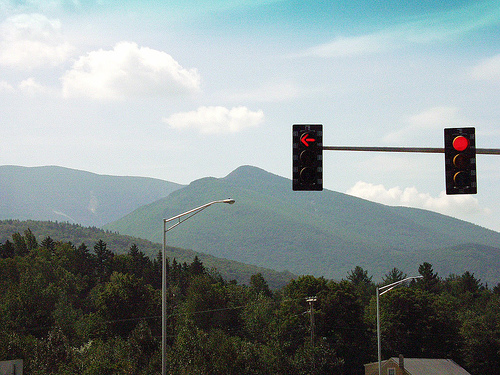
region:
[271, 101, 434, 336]
a traffic light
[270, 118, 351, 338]
a traffic light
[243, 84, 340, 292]
a traffic light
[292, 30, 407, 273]
a traffic light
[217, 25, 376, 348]
a traffic light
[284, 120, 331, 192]
A traffic light with a red arrow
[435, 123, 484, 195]
A black traffic light with a red light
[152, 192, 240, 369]
A metal light post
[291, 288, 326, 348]
A telephone pole among the trees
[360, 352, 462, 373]
The roof of a yellow house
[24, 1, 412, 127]
A cloudy blue sky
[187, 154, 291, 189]
The tip of a mountain in the distance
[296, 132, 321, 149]
A lit up red arrow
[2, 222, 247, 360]
A collection of tall trees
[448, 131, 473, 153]
The red light on a traffic light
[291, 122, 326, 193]
Traffic light with red arrow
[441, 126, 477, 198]
Traffic light on red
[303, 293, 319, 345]
Power line pole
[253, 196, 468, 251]
Tree covered mountain top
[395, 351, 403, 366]
Brick roof top chimney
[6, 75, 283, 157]
Clouds in the sky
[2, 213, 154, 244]
Tree abundant mountain ridge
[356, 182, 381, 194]
Thick white fluffy looking cloud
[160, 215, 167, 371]
Tall metal light pole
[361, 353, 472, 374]
Top portion of a house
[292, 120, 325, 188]
red left turn signal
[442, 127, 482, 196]
a red stop light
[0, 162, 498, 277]
two taller hills behind a lower one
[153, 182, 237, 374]
a steel street light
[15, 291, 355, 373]
a utility pole with power line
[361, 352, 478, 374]
roof of a home with raised rear roof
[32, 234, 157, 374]
Lush green trees along a road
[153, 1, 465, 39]
Turquoise blue ski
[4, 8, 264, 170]
culumus clouds in a hazy portion of sky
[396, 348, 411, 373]
a chimney of a home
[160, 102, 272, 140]
a white cloud in the sky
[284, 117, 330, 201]
a bank of traffic lights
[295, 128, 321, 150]
a left turn stop light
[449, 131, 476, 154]
a red stop light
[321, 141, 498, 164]
a metal traffic light pole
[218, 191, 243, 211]
a street light on the pole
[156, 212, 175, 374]
a gray metal lamp post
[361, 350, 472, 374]
a yellow building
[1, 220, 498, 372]
a group of green trees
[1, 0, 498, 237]
a cloudy blue sky